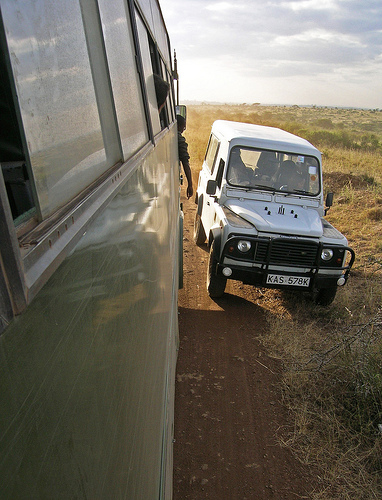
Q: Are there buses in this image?
A: Yes, there is a bus.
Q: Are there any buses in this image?
A: Yes, there is a bus.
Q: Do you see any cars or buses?
A: Yes, there is a bus.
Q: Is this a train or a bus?
A: This is a bus.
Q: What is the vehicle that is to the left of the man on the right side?
A: The vehicle is a bus.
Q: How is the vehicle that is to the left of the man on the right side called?
A: The vehicle is a bus.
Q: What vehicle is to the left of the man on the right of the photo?
A: The vehicle is a bus.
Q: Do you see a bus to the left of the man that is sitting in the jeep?
A: Yes, there is a bus to the left of the man.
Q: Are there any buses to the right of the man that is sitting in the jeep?
A: No, the bus is to the left of the man.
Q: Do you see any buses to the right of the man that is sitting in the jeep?
A: No, the bus is to the left of the man.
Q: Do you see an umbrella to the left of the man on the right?
A: No, there is a bus to the left of the man.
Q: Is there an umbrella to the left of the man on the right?
A: No, there is a bus to the left of the man.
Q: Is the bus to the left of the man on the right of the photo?
A: Yes, the bus is to the left of the man.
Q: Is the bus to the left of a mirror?
A: No, the bus is to the left of the man.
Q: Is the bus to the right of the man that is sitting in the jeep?
A: No, the bus is to the left of the man.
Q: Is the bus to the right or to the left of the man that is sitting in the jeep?
A: The bus is to the left of the man.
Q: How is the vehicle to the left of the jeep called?
A: The vehicle is a bus.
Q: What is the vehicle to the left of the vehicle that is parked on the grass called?
A: The vehicle is a bus.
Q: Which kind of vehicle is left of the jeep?
A: The vehicle is a bus.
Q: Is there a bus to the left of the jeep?
A: Yes, there is a bus to the left of the jeep.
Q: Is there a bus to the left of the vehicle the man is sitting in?
A: Yes, there is a bus to the left of the jeep.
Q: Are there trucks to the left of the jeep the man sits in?
A: No, there is a bus to the left of the jeep.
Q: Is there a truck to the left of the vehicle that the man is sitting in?
A: No, there is a bus to the left of the jeep.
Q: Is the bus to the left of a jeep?
A: Yes, the bus is to the left of a jeep.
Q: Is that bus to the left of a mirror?
A: No, the bus is to the left of a jeep.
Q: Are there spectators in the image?
A: No, there are no spectators.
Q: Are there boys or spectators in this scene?
A: No, there are no spectators or boys.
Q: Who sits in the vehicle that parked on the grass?
A: The man sits in the jeep.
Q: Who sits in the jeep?
A: The man sits in the jeep.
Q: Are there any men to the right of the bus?
A: Yes, there is a man to the right of the bus.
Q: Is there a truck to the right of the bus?
A: No, there is a man to the right of the bus.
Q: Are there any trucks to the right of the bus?
A: No, there is a man to the right of the bus.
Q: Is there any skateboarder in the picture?
A: No, there are no skateboarders.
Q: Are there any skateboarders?
A: No, there are no skateboarders.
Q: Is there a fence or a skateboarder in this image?
A: No, there are no skateboarders or fences.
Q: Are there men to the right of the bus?
A: Yes, there is a man to the right of the bus.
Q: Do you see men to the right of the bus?
A: Yes, there is a man to the right of the bus.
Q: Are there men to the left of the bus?
A: No, the man is to the right of the bus.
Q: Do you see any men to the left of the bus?
A: No, the man is to the right of the bus.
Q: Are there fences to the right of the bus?
A: No, there is a man to the right of the bus.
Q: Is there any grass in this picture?
A: Yes, there is grass.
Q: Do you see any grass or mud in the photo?
A: Yes, there is grass.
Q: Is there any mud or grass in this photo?
A: Yes, there is grass.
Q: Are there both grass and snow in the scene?
A: No, there is grass but no snow.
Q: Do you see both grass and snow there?
A: No, there is grass but no snow.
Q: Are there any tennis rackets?
A: No, there are no tennis rackets.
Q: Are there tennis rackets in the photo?
A: No, there are no tennis rackets.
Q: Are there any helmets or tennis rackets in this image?
A: No, there are no tennis rackets or helmets.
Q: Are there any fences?
A: No, there are no fences.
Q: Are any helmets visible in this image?
A: No, there are no helmets.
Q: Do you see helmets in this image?
A: No, there are no helmets.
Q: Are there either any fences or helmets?
A: No, there are no helmets or fences.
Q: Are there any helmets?
A: No, there are no helmets.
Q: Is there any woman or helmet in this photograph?
A: No, there are no helmets or women.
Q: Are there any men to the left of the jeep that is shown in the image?
A: Yes, there is a man to the left of the jeep.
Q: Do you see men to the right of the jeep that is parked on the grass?
A: No, the man is to the left of the jeep.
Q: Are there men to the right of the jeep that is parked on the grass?
A: No, the man is to the left of the jeep.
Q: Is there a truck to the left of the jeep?
A: No, there is a man to the left of the jeep.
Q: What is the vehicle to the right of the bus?
A: The vehicle is a jeep.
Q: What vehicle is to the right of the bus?
A: The vehicle is a jeep.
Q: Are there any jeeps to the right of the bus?
A: Yes, there is a jeep to the right of the bus.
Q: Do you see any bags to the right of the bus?
A: No, there is a jeep to the right of the bus.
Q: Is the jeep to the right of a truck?
A: No, the jeep is to the right of the bus.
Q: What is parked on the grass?
A: The jeep is parked on the grass.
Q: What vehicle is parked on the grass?
A: The vehicle is a jeep.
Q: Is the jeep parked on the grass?
A: Yes, the jeep is parked on the grass.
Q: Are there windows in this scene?
A: Yes, there are windows.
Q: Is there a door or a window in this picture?
A: Yes, there are windows.